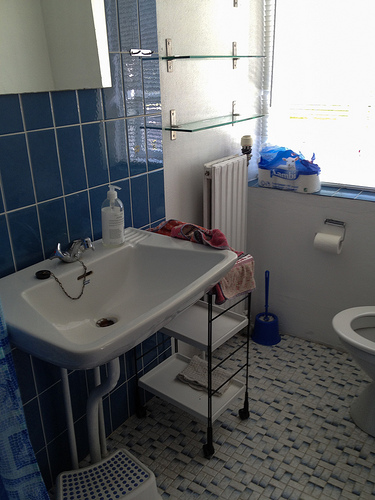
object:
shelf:
[154, 53, 269, 59]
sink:
[0, 207, 238, 372]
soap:
[100, 223, 128, 246]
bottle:
[98, 184, 129, 247]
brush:
[251, 269, 284, 345]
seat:
[330, 301, 375, 360]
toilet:
[331, 301, 374, 442]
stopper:
[35, 269, 53, 281]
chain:
[50, 258, 87, 301]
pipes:
[85, 358, 123, 466]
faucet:
[47, 238, 97, 267]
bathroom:
[1, 0, 374, 500]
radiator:
[202, 153, 253, 333]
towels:
[153, 218, 258, 298]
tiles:
[270, 444, 299, 482]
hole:
[93, 315, 119, 329]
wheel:
[201, 442, 216, 458]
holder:
[130, 249, 259, 458]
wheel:
[238, 407, 250, 422]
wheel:
[134, 406, 150, 421]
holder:
[312, 219, 351, 253]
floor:
[209, 352, 373, 499]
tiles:
[20, 120, 64, 204]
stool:
[55, 443, 163, 500]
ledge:
[0, 225, 148, 295]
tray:
[137, 349, 248, 424]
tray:
[159, 299, 253, 353]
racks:
[159, 103, 264, 137]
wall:
[0, 0, 241, 445]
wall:
[243, 186, 372, 358]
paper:
[258, 138, 325, 193]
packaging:
[259, 141, 324, 192]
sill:
[247, 169, 374, 204]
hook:
[130, 47, 155, 59]